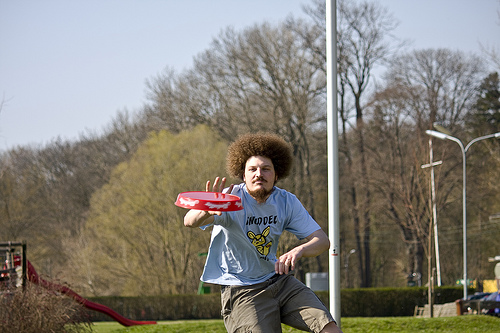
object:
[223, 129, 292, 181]
afro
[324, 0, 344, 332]
pole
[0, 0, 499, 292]
tree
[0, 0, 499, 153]
blue sky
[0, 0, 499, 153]
white clouds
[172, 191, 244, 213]
frisbee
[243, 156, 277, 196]
face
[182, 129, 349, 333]
boy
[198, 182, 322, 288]
tshirt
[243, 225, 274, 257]
cartoon character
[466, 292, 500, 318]
car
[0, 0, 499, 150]
cloud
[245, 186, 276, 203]
goatee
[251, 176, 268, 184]
mustache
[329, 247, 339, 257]
sticker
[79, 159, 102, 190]
branches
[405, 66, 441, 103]
branches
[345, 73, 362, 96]
branches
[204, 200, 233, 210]
shape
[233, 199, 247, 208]
shape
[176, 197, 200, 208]
shape